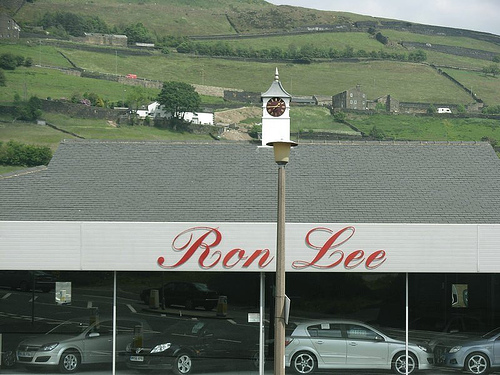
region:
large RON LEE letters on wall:
[150, 215, 389, 278]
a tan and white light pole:
[265, 140, 300, 370]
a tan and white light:
[268, 139, 300, 161]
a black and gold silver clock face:
[265, 93, 284, 115]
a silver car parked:
[286, 317, 432, 372]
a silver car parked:
[18, 310, 150, 366]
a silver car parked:
[436, 330, 498, 368]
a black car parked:
[125, 308, 274, 370]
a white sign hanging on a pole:
[279, 293, 294, 323]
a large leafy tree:
[160, 78, 203, 125]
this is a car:
[298, 317, 405, 357]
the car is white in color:
[336, 342, 376, 359]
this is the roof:
[321, 146, 476, 207]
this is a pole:
[403, 272, 412, 354]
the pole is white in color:
[404, 303, 409, 320]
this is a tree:
[162, 78, 191, 129]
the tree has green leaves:
[169, 84, 191, 103]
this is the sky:
[416, 4, 473, 19]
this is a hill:
[206, 11, 310, 33]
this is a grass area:
[35, 67, 58, 82]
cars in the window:
[2, 282, 493, 369]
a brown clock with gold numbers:
[244, 57, 298, 134]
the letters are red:
[132, 206, 399, 284]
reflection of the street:
[0, 272, 247, 347]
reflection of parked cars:
[5, 257, 233, 360]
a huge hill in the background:
[53, 0, 399, 66]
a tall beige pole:
[242, 122, 312, 366]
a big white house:
[105, 71, 225, 131]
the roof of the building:
[32, 136, 490, 223]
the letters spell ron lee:
[101, 205, 391, 281]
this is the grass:
[304, 65, 344, 85]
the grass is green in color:
[314, 70, 368, 83]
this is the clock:
[264, 92, 291, 122]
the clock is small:
[266, 97, 286, 117]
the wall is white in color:
[264, 120, 286, 132]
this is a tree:
[159, 82, 200, 129]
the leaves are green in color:
[169, 81, 196, 106]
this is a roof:
[336, 143, 491, 222]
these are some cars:
[21, 300, 498, 369]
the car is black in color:
[203, 335, 233, 360]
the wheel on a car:
[289, 347, 322, 373]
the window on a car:
[344, 318, 386, 342]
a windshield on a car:
[44, 314, 96, 339]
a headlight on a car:
[149, 338, 175, 353]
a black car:
[123, 311, 263, 373]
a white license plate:
[127, 355, 145, 364]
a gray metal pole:
[398, 269, 410, 374]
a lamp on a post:
[262, 129, 304, 172]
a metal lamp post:
[266, 164, 289, 374]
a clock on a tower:
[264, 92, 288, 119]